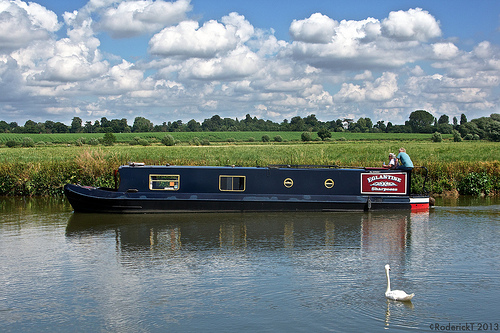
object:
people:
[394, 146, 416, 171]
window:
[148, 173, 180, 191]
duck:
[382, 263, 417, 303]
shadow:
[66, 209, 407, 250]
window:
[219, 175, 232, 191]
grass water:
[0, 151, 500, 197]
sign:
[359, 171, 408, 197]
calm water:
[0, 192, 500, 331]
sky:
[0, 0, 500, 123]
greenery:
[0, 111, 500, 197]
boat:
[58, 160, 437, 214]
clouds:
[287, 12, 342, 46]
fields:
[0, 130, 500, 196]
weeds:
[456, 172, 498, 200]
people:
[382, 152, 400, 171]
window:
[326, 183, 335, 188]